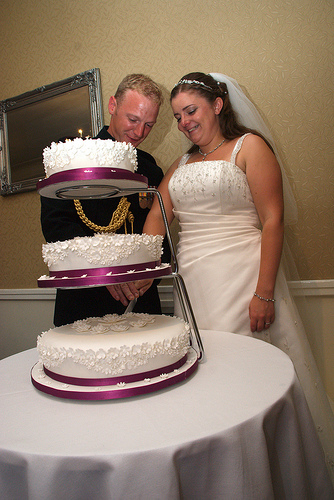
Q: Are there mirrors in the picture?
A: Yes, there is a mirror.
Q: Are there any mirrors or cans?
A: Yes, there is a mirror.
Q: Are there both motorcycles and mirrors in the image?
A: No, there is a mirror but no motorcycles.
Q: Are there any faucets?
A: No, there are no faucets.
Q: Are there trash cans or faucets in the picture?
A: No, there are no faucets or trash cans.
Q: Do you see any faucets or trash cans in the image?
A: No, there are no faucets or trash cans.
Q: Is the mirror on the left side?
A: Yes, the mirror is on the left of the image.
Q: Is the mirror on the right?
A: No, the mirror is on the left of the image.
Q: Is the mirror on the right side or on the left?
A: The mirror is on the left of the image.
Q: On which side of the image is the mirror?
A: The mirror is on the left of the image.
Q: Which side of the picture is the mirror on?
A: The mirror is on the left of the image.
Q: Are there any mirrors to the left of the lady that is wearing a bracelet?
A: Yes, there is a mirror to the left of the lady.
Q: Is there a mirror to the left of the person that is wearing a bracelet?
A: Yes, there is a mirror to the left of the lady.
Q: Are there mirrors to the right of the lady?
A: No, the mirror is to the left of the lady.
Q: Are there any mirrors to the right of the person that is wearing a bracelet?
A: No, the mirror is to the left of the lady.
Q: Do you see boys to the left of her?
A: No, there is a mirror to the left of the lady.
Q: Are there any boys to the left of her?
A: No, there is a mirror to the left of the lady.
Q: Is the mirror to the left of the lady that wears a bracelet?
A: Yes, the mirror is to the left of the lady.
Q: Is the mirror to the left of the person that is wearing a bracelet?
A: Yes, the mirror is to the left of the lady.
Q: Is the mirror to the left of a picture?
A: No, the mirror is to the left of the lady.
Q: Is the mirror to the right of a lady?
A: No, the mirror is to the left of a lady.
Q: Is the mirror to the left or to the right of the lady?
A: The mirror is to the left of the lady.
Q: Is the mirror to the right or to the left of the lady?
A: The mirror is to the left of the lady.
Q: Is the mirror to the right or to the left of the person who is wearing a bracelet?
A: The mirror is to the left of the lady.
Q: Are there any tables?
A: Yes, there is a table.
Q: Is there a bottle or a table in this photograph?
A: Yes, there is a table.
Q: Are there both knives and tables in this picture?
A: Yes, there are both a table and a knife.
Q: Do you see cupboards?
A: No, there are no cupboards.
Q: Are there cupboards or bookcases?
A: No, there are no cupboards or bookcases.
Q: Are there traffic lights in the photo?
A: No, there are no traffic lights.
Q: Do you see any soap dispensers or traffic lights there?
A: No, there are no traffic lights or soap dispensers.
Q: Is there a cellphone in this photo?
A: No, there are no cell phones.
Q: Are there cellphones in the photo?
A: No, there are no cellphones.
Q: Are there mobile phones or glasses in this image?
A: No, there are no mobile phones or glasses.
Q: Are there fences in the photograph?
A: No, there are no fences.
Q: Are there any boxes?
A: No, there are no boxes.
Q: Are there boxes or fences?
A: No, there are no boxes or fences.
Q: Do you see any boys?
A: No, there are no boys.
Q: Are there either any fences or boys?
A: No, there are no boys or fences.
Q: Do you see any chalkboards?
A: No, there are no chalkboards.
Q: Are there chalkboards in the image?
A: No, there are no chalkboards.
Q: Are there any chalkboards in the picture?
A: No, there are no chalkboards.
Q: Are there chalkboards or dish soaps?
A: No, there are no chalkboards or dish soaps.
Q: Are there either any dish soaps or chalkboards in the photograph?
A: No, there are no chalkboards or dish soaps.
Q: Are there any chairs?
A: No, there are no chairs.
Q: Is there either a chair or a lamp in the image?
A: No, there are no chairs or lamps.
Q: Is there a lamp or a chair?
A: No, there are no chairs or lamps.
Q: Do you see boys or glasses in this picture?
A: No, there are no boys or glasses.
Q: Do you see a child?
A: No, there are no children.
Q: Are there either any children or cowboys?
A: No, there are no children or cowboys.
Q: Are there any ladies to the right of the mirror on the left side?
A: Yes, there is a lady to the right of the mirror.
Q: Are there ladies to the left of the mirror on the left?
A: No, the lady is to the right of the mirror.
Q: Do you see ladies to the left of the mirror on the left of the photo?
A: No, the lady is to the right of the mirror.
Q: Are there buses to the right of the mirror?
A: No, there is a lady to the right of the mirror.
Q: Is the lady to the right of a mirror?
A: Yes, the lady is to the right of a mirror.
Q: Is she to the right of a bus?
A: No, the lady is to the right of a mirror.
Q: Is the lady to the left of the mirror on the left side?
A: No, the lady is to the right of the mirror.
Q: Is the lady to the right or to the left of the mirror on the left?
A: The lady is to the right of the mirror.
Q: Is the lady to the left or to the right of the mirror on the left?
A: The lady is to the right of the mirror.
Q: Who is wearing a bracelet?
A: The lady is wearing a bracelet.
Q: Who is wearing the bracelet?
A: The lady is wearing a bracelet.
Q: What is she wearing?
A: The lady is wearing a bracelet.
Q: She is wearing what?
A: The lady is wearing a bracelet.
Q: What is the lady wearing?
A: The lady is wearing a bracelet.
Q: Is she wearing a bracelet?
A: Yes, the lady is wearing a bracelet.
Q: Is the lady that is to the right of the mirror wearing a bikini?
A: No, the lady is wearing a bracelet.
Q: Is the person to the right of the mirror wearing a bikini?
A: No, the lady is wearing a bracelet.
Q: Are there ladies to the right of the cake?
A: Yes, there is a lady to the right of the cake.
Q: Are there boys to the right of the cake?
A: No, there is a lady to the right of the cake.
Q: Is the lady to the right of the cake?
A: Yes, the lady is to the right of the cake.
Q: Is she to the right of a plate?
A: No, the lady is to the right of the cake.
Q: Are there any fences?
A: No, there are no fences.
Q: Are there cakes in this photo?
A: Yes, there is a cake.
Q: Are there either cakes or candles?
A: Yes, there is a cake.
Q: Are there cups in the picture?
A: No, there are no cups.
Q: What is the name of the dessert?
A: The dessert is a cake.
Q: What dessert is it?
A: The dessert is a cake.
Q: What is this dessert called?
A: This is a cake.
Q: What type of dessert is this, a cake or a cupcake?
A: This is a cake.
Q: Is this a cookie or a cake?
A: This is a cake.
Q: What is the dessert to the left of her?
A: The dessert is a cake.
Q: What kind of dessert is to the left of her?
A: The dessert is a cake.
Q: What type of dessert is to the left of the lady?
A: The dessert is a cake.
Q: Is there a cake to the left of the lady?
A: Yes, there is a cake to the left of the lady.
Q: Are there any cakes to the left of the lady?
A: Yes, there is a cake to the left of the lady.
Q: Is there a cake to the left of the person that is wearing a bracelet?
A: Yes, there is a cake to the left of the lady.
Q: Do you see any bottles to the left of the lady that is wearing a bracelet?
A: No, there is a cake to the left of the lady.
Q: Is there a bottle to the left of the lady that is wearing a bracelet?
A: No, there is a cake to the left of the lady.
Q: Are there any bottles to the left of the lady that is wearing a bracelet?
A: No, there is a cake to the left of the lady.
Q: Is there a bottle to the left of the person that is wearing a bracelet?
A: No, there is a cake to the left of the lady.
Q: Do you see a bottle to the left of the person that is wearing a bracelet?
A: No, there is a cake to the left of the lady.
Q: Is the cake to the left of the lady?
A: Yes, the cake is to the left of the lady.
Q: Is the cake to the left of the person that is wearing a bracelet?
A: Yes, the cake is to the left of the lady.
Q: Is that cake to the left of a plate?
A: No, the cake is to the left of the lady.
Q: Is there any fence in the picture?
A: No, there are no fences.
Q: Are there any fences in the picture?
A: No, there are no fences.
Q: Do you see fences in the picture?
A: No, there are no fences.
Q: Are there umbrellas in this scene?
A: No, there are no umbrellas.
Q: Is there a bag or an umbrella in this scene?
A: No, there are no umbrellas or bags.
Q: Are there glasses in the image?
A: No, there are no glasses.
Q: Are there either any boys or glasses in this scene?
A: No, there are no glasses or boys.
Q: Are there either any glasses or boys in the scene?
A: No, there are no glasses or boys.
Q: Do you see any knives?
A: Yes, there is a knife.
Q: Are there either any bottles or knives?
A: Yes, there is a knife.